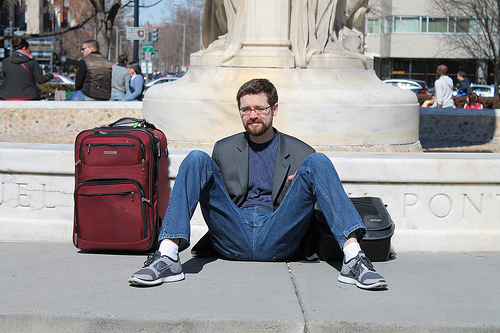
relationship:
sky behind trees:
[115, 0, 188, 30] [64, 2, 217, 78]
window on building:
[392, 11, 423, 31] [361, 2, 498, 95]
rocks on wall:
[4, 107, 149, 147] [4, 99, 159, 150]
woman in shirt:
[122, 49, 148, 103] [122, 71, 146, 102]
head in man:
[230, 73, 282, 138] [124, 77, 387, 290]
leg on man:
[154, 150, 254, 266] [124, 77, 387, 290]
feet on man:
[129, 250, 191, 286] [124, 77, 387, 290]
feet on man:
[337, 245, 391, 291] [124, 77, 387, 290]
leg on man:
[260, 153, 389, 296] [124, 77, 387, 290]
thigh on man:
[197, 172, 251, 261] [124, 77, 387, 290]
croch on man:
[233, 202, 274, 266] [124, 77, 387, 290]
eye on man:
[238, 100, 249, 117] [124, 77, 387, 290]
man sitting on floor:
[130, 77, 388, 291] [0, 240, 499, 328]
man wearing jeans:
[130, 77, 388, 291] [153, 148, 368, 253]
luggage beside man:
[309, 194, 393, 264] [130, 77, 388, 291]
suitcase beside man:
[72, 114, 172, 250] [130, 77, 388, 291]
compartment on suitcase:
[72, 178, 152, 246] [72, 114, 172, 250]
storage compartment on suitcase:
[74, 180, 151, 243] [72, 114, 172, 250]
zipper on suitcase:
[72, 175, 151, 242] [72, 114, 172, 250]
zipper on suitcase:
[82, 141, 137, 149] [72, 114, 172, 250]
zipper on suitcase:
[75, 186, 140, 198] [72, 114, 172, 250]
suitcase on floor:
[71, 115, 173, 252] [0, 240, 499, 328]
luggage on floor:
[314, 194, 393, 258] [0, 240, 499, 328]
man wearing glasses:
[130, 77, 388, 291] [235, 104, 272, 117]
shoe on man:
[336, 248, 386, 288] [130, 77, 388, 291]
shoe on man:
[127, 251, 184, 285] [130, 77, 388, 291]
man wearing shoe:
[130, 77, 388, 291] [338, 249, 389, 291]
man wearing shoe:
[130, 77, 388, 291] [127, 248, 187, 288]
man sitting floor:
[130, 77, 388, 291] [0, 240, 499, 328]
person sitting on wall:
[0, 30, 60, 100] [0, 98, 144, 144]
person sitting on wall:
[64, 39, 112, 100] [0, 98, 144, 144]